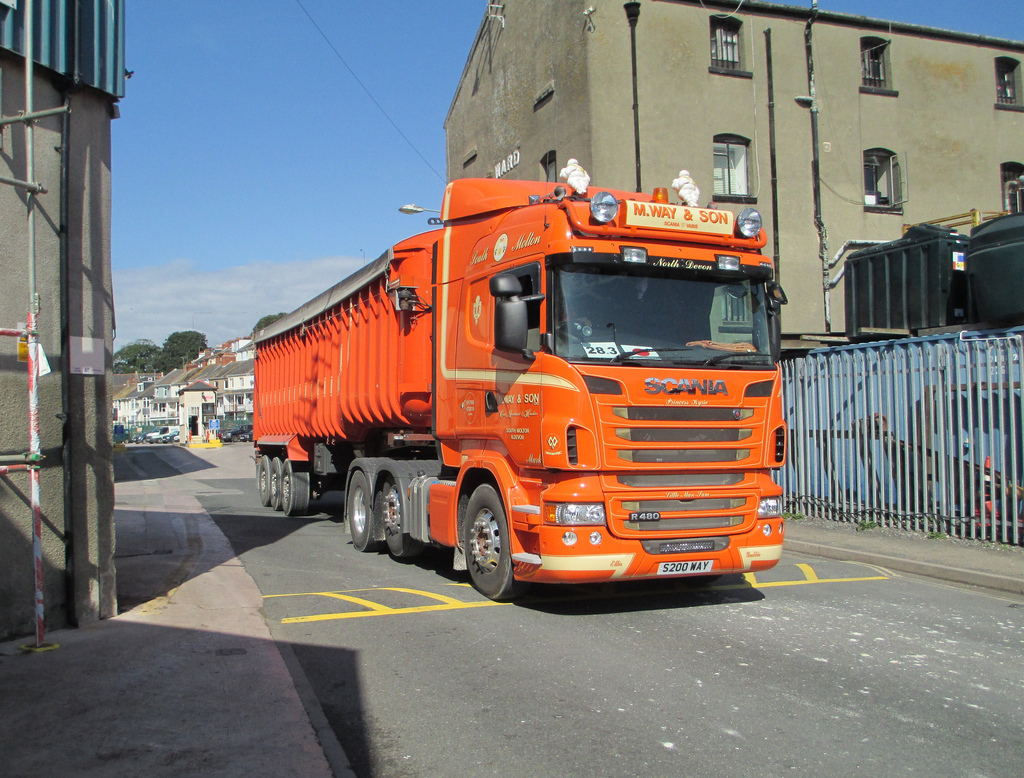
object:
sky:
[175, 68, 225, 116]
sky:
[211, 98, 288, 166]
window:
[859, 113, 909, 190]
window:
[859, 22, 898, 85]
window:
[701, 16, 740, 65]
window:
[699, 145, 751, 184]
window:
[866, 160, 894, 205]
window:
[991, 60, 1019, 99]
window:
[1004, 163, 1021, 201]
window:
[537, 157, 545, 189]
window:
[230, 390, 239, 404]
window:
[143, 397, 170, 417]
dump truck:
[258, 168, 789, 608]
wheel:
[443, 482, 511, 595]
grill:
[603, 397, 754, 539]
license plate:
[654, 548, 723, 582]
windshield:
[539, 253, 785, 362]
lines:
[262, 525, 895, 649]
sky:
[280, 115, 444, 235]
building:
[438, 22, 573, 199]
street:
[187, 400, 1008, 775]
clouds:
[99, 248, 168, 298]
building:
[654, 37, 922, 225]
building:
[827, 207, 988, 340]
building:
[198, 364, 255, 459]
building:
[120, 371, 188, 434]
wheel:
[250, 444, 272, 505]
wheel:
[265, 446, 287, 507]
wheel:
[277, 458, 313, 511]